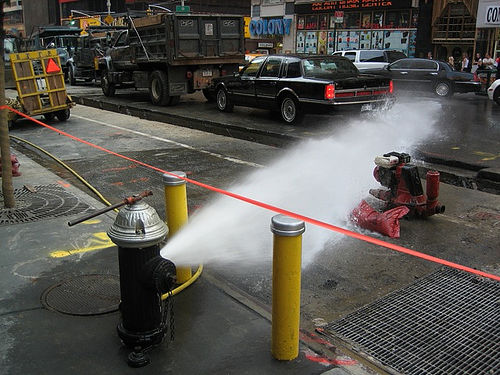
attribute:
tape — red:
[6, 101, 498, 281]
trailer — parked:
[6, 45, 74, 123]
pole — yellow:
[267, 210, 306, 360]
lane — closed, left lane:
[82, 96, 400, 321]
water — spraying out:
[159, 87, 448, 267]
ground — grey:
[441, 145, 459, 178]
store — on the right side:
[287, 9, 494, 83]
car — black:
[203, 52, 393, 123]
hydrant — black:
[58, 165, 196, 337]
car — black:
[196, 46, 400, 128]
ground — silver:
[384, 211, 402, 228]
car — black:
[237, 56, 372, 116]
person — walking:
[447, 52, 455, 71]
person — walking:
[457, 50, 469, 72]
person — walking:
[473, 48, 480, 65]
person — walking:
[479, 46, 493, 66]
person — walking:
[426, 49, 433, 60]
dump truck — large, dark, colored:
[93, 38, 230, 96]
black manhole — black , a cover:
[42, 272, 125, 317]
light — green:
[327, 81, 390, 98]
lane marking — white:
[71, 108, 266, 168]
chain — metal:
[156, 284, 182, 313]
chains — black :
[154, 263, 177, 342]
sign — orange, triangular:
[263, 197, 333, 341]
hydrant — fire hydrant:
[102, 191, 182, 366]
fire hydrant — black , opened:
[98, 183, 180, 373]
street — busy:
[9, 80, 499, 372]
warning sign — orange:
[44, 59, 60, 73]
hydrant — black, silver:
[114, 210, 214, 335]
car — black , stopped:
[194, 44, 403, 133]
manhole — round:
[41, 272, 127, 317]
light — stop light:
[67, 12, 78, 26]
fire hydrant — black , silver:
[105, 195, 179, 365]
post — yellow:
[139, 137, 370, 374]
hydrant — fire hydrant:
[101, 174, 223, 334]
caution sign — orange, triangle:
[39, 53, 63, 79]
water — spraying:
[277, 167, 333, 265]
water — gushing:
[156, 97, 444, 277]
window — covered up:
[285, 16, 451, 84]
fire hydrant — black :
[81, 186, 169, 347]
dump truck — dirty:
[89, 3, 248, 113]